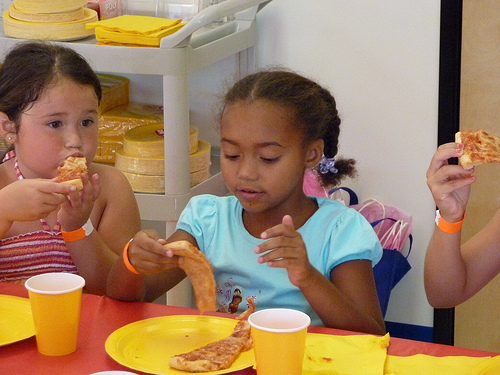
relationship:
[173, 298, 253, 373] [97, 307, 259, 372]
pizza on plate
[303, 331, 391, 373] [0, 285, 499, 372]
napkin on table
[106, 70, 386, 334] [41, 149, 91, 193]
child eats pizza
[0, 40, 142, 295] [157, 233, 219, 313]
child eats pizza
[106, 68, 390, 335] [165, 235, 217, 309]
child holds pizza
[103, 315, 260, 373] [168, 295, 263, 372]
plate holding pizza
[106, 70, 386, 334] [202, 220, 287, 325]
child wearing shirt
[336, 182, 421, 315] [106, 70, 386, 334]
bags behind child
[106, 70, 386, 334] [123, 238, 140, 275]
child wearing bracelet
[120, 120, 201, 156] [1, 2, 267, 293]
paper plates stacked on a cart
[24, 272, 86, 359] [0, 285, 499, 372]
cup on table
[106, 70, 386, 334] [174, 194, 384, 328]
child wearing a shirt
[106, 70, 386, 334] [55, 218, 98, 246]
child wearing a band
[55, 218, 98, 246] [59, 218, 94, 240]
band around band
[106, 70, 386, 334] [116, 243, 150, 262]
child wearing bracelet